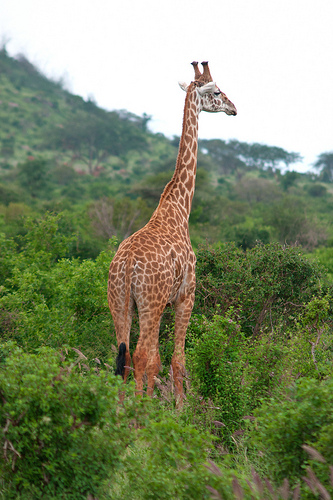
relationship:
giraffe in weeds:
[99, 52, 246, 420] [1, 317, 332, 498]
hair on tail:
[109, 340, 129, 380] [102, 246, 147, 379]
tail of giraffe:
[102, 246, 147, 379] [99, 52, 246, 420]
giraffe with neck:
[99, 52, 246, 420] [165, 99, 209, 224]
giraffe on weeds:
[99, 52, 246, 420] [1, 317, 332, 498]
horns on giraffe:
[191, 58, 212, 81] [99, 52, 246, 420]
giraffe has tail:
[99, 52, 246, 420] [102, 246, 147, 379]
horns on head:
[191, 58, 212, 81] [181, 65, 240, 126]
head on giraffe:
[181, 65, 240, 126] [99, 52, 246, 420]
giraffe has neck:
[99, 52, 246, 420] [165, 99, 209, 224]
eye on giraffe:
[214, 91, 226, 102] [99, 52, 246, 420]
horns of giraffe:
[191, 58, 212, 81] [99, 52, 246, 420]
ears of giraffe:
[193, 77, 205, 91] [99, 52, 246, 420]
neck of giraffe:
[165, 99, 209, 224] [99, 52, 246, 420]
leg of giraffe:
[172, 292, 199, 406] [99, 52, 246, 420]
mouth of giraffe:
[225, 105, 238, 119] [99, 52, 246, 420]